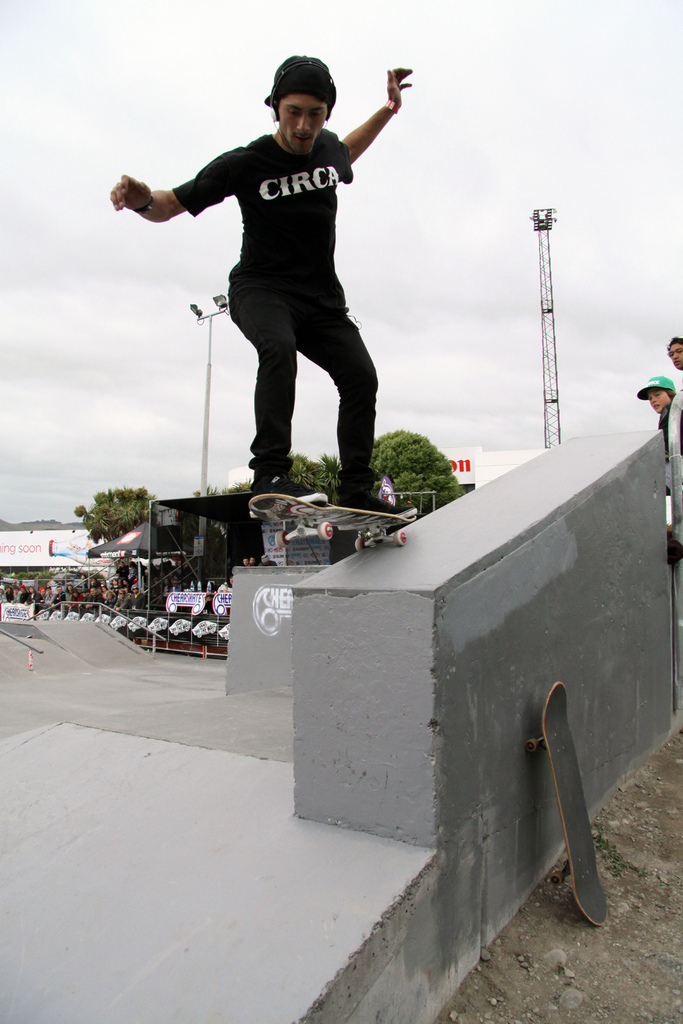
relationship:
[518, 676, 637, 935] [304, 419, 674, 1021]
skateboard leaning on wall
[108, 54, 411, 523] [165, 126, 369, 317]
guy wearing shirt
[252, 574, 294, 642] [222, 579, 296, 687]
letters on wall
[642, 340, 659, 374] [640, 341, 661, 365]
person has hair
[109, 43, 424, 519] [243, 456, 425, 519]
person wearing tennis shoes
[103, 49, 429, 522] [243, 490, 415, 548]
guy on skateboard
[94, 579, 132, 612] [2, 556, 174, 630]
spectators sitting in stand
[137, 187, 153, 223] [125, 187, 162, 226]
watch band on wrist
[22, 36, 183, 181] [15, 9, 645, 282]
clouds in sky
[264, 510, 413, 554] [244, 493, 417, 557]
wheels on skateboard